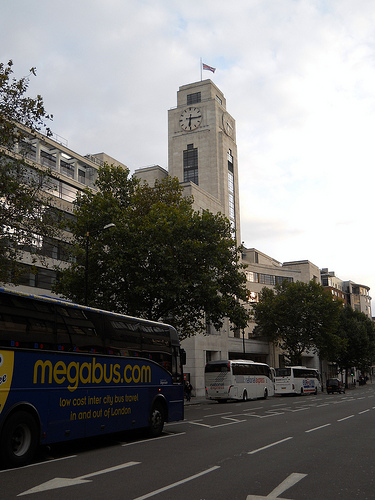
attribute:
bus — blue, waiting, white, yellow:
[1, 286, 186, 462]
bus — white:
[205, 358, 278, 402]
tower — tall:
[168, 78, 240, 241]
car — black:
[329, 379, 344, 393]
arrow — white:
[15, 458, 141, 498]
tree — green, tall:
[55, 162, 253, 339]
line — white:
[249, 433, 295, 455]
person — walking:
[183, 377, 193, 402]